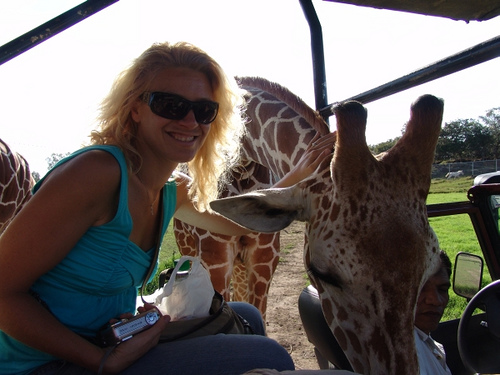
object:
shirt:
[0, 137, 183, 366]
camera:
[105, 303, 165, 342]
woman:
[1, 38, 351, 375]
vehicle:
[0, 1, 499, 373]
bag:
[129, 249, 253, 346]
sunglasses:
[144, 89, 230, 125]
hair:
[84, 37, 254, 219]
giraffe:
[169, 69, 457, 375]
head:
[203, 90, 463, 375]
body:
[165, 72, 327, 328]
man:
[399, 245, 466, 375]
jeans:
[34, 296, 300, 373]